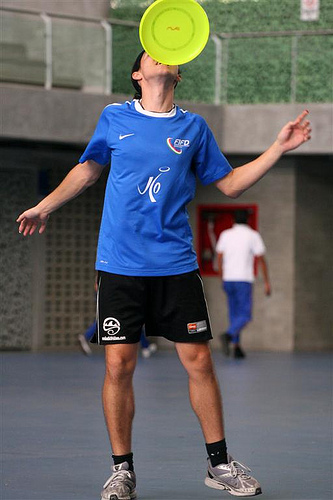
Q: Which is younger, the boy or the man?
A: The boy is younger than the man.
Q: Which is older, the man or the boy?
A: The man is older than the boy.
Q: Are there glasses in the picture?
A: No, there are no glasses.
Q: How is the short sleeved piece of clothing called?
A: The clothing item is a shirt.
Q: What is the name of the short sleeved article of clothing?
A: The clothing item is a shirt.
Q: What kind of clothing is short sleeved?
A: The clothing is a shirt.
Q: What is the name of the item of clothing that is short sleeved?
A: The clothing item is a shirt.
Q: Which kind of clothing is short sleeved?
A: The clothing is a shirt.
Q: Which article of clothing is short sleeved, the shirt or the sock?
A: The shirt is short sleeved.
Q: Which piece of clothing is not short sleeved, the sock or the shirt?
A: The sock is not short sleeved.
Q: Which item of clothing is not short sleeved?
A: The clothing item is a sock.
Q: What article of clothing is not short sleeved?
A: The clothing item is a sock.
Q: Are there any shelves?
A: No, there are no shelves.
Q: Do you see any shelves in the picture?
A: No, there are no shelves.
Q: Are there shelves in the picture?
A: No, there are no shelves.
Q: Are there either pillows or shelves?
A: No, there are no shelves or pillows.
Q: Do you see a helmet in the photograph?
A: No, there are no helmets.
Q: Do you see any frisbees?
A: Yes, there is a frisbee.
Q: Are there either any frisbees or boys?
A: Yes, there is a frisbee.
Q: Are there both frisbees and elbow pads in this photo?
A: No, there is a frisbee but no elbow pads.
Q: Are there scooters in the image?
A: No, there are no scooters.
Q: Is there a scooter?
A: No, there are no scooters.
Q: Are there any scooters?
A: No, there are no scooters.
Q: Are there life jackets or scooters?
A: No, there are no scooters or life jackets.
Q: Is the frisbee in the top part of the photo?
A: Yes, the frisbee is in the top of the image.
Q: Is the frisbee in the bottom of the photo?
A: No, the frisbee is in the top of the image.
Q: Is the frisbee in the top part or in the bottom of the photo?
A: The frisbee is in the top of the image.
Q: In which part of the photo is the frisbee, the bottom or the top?
A: The frisbee is in the top of the image.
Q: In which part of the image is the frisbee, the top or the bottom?
A: The frisbee is in the top of the image.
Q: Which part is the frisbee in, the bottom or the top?
A: The frisbee is in the top of the image.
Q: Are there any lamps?
A: No, there are no lamps.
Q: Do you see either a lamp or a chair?
A: No, there are no lamps or chairs.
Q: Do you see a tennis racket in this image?
A: No, there are no rackets.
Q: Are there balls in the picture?
A: No, there are no balls.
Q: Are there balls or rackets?
A: No, there are no balls or rackets.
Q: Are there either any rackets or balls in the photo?
A: No, there are no balls or rackets.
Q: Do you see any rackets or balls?
A: No, there are no balls or rackets.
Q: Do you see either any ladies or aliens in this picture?
A: No, there are no ladies or aliens.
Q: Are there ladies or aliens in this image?
A: No, there are no ladies or aliens.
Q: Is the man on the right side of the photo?
A: Yes, the man is on the right of the image.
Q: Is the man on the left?
A: No, the man is on the right of the image.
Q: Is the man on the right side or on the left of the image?
A: The man is on the right of the image.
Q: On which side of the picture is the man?
A: The man is on the right of the image.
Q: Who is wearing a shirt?
A: The man is wearing a shirt.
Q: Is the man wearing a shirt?
A: Yes, the man is wearing a shirt.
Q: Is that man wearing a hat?
A: No, the man is wearing a shirt.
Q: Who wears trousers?
A: The man wears trousers.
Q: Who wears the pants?
A: The man wears trousers.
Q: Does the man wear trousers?
A: Yes, the man wears trousers.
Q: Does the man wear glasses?
A: No, the man wears trousers.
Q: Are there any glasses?
A: No, there are no glasses.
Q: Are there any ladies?
A: No, there are no ladies.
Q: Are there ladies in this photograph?
A: No, there are no ladies.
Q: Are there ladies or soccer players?
A: No, there are no ladies or soccer players.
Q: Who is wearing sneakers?
A: The boy is wearing sneakers.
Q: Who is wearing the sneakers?
A: The boy is wearing sneakers.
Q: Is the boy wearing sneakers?
A: Yes, the boy is wearing sneakers.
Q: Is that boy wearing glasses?
A: No, the boy is wearing sneakers.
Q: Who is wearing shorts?
A: The boy is wearing shorts.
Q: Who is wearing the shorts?
A: The boy is wearing shorts.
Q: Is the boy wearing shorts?
A: Yes, the boy is wearing shorts.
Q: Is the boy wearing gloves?
A: No, the boy is wearing shorts.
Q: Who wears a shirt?
A: The boy wears a shirt.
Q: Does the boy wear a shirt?
A: Yes, the boy wears a shirt.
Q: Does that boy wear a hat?
A: No, the boy wears a shirt.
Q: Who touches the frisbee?
A: The boy touches the frisbee.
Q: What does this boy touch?
A: The boy touches the frisbee.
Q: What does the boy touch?
A: The boy touches the frisbee.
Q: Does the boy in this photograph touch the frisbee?
A: Yes, the boy touches the frisbee.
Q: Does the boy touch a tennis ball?
A: No, the boy touches the frisbee.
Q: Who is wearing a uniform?
A: The boy is wearing a uniform.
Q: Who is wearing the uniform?
A: The boy is wearing a uniform.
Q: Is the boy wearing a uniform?
A: Yes, the boy is wearing a uniform.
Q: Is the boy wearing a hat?
A: No, the boy is wearing a uniform.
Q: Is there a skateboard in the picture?
A: No, there are no skateboards.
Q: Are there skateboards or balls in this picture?
A: No, there are no skateboards or balls.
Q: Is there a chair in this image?
A: No, there are no chairs.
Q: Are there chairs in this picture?
A: No, there are no chairs.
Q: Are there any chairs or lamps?
A: No, there are no chairs or lamps.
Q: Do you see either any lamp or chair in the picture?
A: No, there are no chairs or lamps.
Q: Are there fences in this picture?
A: Yes, there is a fence.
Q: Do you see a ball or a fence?
A: Yes, there is a fence.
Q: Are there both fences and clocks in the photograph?
A: No, there is a fence but no clocks.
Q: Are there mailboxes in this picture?
A: No, there are no mailboxes.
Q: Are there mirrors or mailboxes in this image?
A: No, there are no mailboxes or mirrors.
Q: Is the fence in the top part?
A: Yes, the fence is in the top of the image.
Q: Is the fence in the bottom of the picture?
A: No, the fence is in the top of the image.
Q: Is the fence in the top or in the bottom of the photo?
A: The fence is in the top of the image.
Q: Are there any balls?
A: No, there are no balls.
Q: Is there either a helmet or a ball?
A: No, there are no balls or helmets.